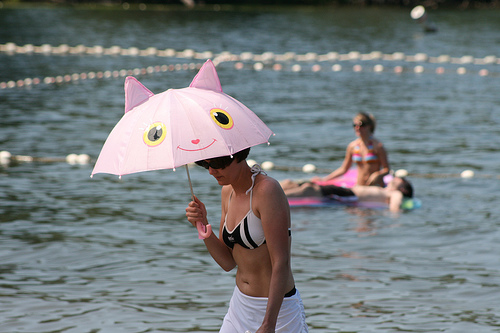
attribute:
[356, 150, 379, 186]
bikini — striped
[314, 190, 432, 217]
guy — on float, floating on raft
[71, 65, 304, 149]
umbrella — hello kitty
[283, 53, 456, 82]
buoys — protection, white, pink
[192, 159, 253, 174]
sunglasses — dark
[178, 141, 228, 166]
smile — pink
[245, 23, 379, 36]
water — in bottom of photo, rippled, blue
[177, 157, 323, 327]
woman — looking down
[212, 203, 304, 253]
bikini top — black, white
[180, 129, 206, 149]
nose — heart, pink heart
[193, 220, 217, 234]
handle — pink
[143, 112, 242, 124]
eyes — yellow, black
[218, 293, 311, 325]
shorts — white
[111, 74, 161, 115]
left ear — pink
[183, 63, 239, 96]
right ear — pink